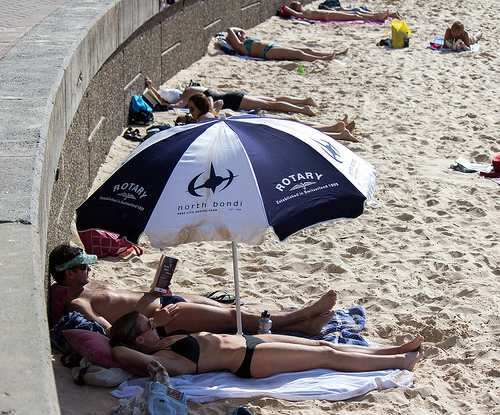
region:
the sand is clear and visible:
[340, 163, 458, 358]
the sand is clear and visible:
[339, 238, 429, 411]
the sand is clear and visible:
[359, 188, 434, 341]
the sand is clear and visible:
[353, 85, 473, 307]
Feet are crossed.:
[369, 332, 438, 373]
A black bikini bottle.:
[234, 330, 266, 389]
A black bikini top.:
[159, 327, 204, 379]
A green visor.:
[52, 237, 99, 278]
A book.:
[145, 246, 180, 297]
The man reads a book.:
[47, 240, 334, 340]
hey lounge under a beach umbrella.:
[47, 81, 439, 403]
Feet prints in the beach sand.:
[407, 178, 489, 291]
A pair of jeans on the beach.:
[134, 382, 193, 413]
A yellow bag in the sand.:
[383, 18, 418, 53]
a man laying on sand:
[41, 243, 337, 337]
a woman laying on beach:
[103, 306, 433, 377]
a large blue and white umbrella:
[64, 109, 377, 329]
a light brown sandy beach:
[65, 0, 492, 412]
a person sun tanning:
[178, 79, 332, 116]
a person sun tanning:
[213, 24, 348, 66]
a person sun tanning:
[275, 0, 392, 27]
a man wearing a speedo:
[50, 244, 333, 333]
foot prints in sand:
[378, 68, 472, 131]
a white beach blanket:
[124, 369, 386, 400]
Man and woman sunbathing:
[41, 240, 437, 387]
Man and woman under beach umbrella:
[51, 108, 432, 403]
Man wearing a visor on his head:
[42, 240, 107, 285]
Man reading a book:
[46, 238, 181, 299]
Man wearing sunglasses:
[42, 240, 103, 287]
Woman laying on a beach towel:
[96, 308, 428, 393]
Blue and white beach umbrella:
[70, 115, 376, 253]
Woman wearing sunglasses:
[105, 307, 162, 347]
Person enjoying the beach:
[202, 20, 352, 72]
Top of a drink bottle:
[253, 306, 275, 333]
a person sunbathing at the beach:
[434, 14, 495, 78]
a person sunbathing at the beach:
[278, 0, 396, 31]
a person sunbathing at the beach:
[218, 18, 353, 83]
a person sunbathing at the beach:
[143, 73, 326, 123]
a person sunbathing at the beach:
[183, 93, 361, 160]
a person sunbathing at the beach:
[46, 240, 341, 335]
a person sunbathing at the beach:
[113, 315, 438, 404]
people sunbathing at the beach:
[46, 0, 497, 407]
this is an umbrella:
[58, 105, 390, 331]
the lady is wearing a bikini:
[113, 310, 434, 391]